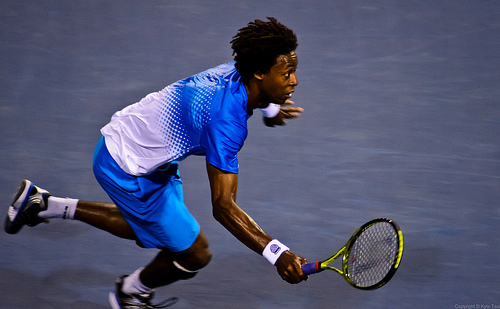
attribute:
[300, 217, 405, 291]
racket — black, tennis racket, yellow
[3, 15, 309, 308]
man — swinging, running, playing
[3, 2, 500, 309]
tennis court — blue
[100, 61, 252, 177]
shirt — white, blue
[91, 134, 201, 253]
shorts — blue, bright blue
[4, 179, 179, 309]
shoes — black,white, tennis shoes, blue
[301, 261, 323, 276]
handle — blue, red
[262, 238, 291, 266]
wristband — white, thick, blue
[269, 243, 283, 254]
symbol — blue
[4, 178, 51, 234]
shoe — black, silver, white, blue, tennis shoe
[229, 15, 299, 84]
hair — dark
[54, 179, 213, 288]
legs — muscular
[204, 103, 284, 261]
arms — muscular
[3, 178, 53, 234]
foot — lifted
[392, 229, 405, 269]
line — yellow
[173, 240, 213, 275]
knee — bent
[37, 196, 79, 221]
sock — white, black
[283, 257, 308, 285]
fingers — wrapped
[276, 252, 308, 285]
hand — gripping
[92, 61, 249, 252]
outfit — tennis outfit